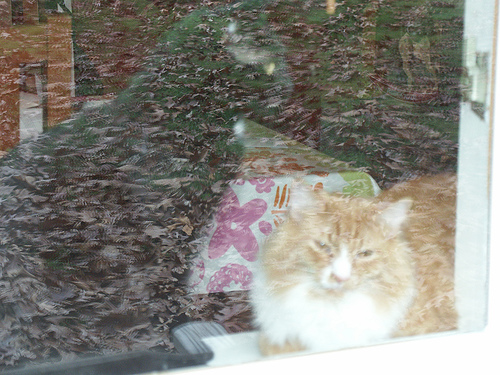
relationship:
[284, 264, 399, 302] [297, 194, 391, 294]
whiskers on face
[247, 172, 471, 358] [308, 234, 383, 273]
cat has eyes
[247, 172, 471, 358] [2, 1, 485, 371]
cat in window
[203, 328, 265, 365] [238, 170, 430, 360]
table under cat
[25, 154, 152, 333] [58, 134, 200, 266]
reflection of leafs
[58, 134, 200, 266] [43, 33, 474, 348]
leafs on window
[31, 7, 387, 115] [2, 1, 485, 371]
leaves reflected in window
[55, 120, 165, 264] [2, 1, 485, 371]
grass reflected in window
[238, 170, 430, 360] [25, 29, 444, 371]
cat sitting in window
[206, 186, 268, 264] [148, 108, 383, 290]
flower on box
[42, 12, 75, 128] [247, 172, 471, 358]
bed post by cat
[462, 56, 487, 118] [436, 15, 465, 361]
latch on wall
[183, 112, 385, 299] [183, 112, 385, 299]
box wrapped in box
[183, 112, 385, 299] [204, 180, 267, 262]
box with floral details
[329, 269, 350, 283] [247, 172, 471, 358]
nose on cat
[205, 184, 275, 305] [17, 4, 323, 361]
designs near cat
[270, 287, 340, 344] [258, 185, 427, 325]
fur on cat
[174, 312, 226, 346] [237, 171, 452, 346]
remote by cat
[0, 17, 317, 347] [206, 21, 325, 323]
cat in window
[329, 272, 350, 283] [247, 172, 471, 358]
nose of cat